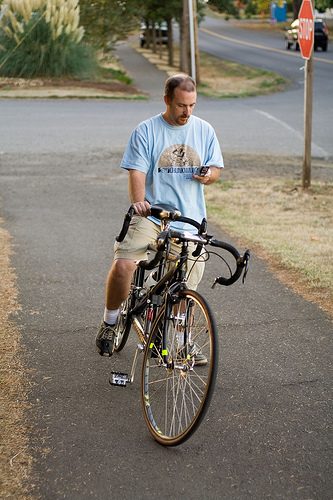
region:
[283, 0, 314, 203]
"A STOP sign is pictured here"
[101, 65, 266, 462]
"A guy and a bike is seen here"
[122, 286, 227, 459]
"The wheel of a bicycle"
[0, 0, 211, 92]
"Trees and plants are pictured here"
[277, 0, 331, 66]
"The STOP sign is red and white"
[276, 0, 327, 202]
"The sign is on a wooden post"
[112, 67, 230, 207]
"The man is looking at his phone"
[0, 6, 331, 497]
"Streets and sidewalks"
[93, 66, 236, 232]
"He is wearing a short sleeved t-shirt"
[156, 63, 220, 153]
"He is not wearing anything on his head"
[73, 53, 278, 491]
guy on the bike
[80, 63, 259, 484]
guy leaning on the bike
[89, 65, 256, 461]
guy on his cellphone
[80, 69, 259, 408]
guy wearing a light blue shirt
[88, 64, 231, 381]
guy wearing beige shorts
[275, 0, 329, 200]
red stop sign posted on wood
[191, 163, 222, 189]
silver cellphone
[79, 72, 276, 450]
guy right hand on the bike handle bar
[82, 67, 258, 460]
guy wearing white socks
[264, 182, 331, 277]
brown grass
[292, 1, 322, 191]
stop sign on the grass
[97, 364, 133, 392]
pedal of the bike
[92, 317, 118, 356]
black and white sneaker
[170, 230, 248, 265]
handle of the bike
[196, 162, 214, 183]
cellphone in the hand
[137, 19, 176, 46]
truck parked on the road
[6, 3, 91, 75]
flowers on the bush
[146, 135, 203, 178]
logo on the blue shirt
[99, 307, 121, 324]
white socks on the guy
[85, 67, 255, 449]
A man on a bicycle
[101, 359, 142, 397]
A bicycle pedal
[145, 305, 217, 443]
A bicycle wheel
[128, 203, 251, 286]
A bicycles handlebars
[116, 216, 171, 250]
A pair of beige shorts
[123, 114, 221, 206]
A blue tee shirt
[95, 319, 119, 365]
Black and beige tennis shoe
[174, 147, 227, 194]
A man using a cellphone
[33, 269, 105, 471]
A paved path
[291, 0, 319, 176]
A red stop sign on a metal pole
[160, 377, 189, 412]
spokes on the bike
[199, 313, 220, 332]
part of the tire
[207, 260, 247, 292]
handle bars on the bike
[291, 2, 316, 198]
stop sign on a pole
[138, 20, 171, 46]
van parked behind trees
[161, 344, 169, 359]
yellow floursent on the bike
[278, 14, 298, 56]
front of black vehicle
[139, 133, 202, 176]
logo on the shirt